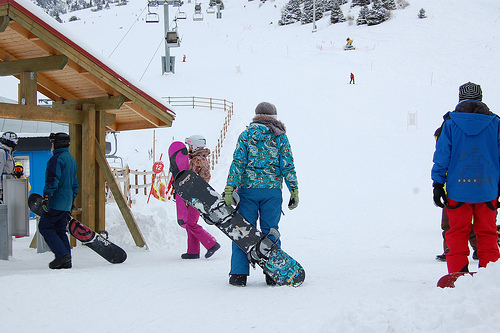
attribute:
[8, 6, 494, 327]
slope — covered with snow, for skiing, white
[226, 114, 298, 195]
parka — blue, colored, varied, patterned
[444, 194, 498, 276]
pants — for snow, red, snow style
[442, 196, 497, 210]
suspenders — attached to pants, hanging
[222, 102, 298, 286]
person — a woman, snowboarder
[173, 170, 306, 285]
snowboard — blue, black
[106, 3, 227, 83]
chairlift — for reaching top, for skiing, for trail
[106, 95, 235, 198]
fencing — wooden, rail style, wood, brown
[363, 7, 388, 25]
pine — snow covered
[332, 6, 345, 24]
pine — snow covered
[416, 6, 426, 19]
pine — snow covered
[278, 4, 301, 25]
pine — snow covered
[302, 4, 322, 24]
pine — snow covered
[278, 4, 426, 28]
cluster — fir, of trees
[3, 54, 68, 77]
beam — for support, wood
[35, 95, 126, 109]
beam — for support, wood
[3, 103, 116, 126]
beam — for support, wood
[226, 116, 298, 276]
outfit — black, teal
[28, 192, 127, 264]
snowboard — red, black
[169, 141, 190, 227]
snowboard — black, pink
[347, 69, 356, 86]
man — snowboarder, wearing red, skiing, wearing jacket, snowboarding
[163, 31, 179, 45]
seat — a basket, for lifting, basket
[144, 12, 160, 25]
seat — a basket, for lifting, basket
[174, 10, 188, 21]
seat — a basket, for lifting, basket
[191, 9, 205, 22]
seat — a basket, for lifting, basket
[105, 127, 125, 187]
seat — a basket, for lifting, basket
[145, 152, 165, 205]
sign — orange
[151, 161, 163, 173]
number — 12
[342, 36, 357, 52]
man — wearing yellow, wearing jacket, skiing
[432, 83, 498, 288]
man — wearing blue, wearing red, person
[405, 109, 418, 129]
marker — for trail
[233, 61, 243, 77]
marker — for trail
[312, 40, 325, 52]
marker — for trail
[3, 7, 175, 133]
roof — platform, wooden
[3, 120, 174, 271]
break area — wood constructed, shelter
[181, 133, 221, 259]
woman — heading, person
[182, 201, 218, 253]
pants — pink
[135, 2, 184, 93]
wire — guy type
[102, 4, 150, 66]
wire — guy type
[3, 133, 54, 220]
building — blue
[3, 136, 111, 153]
roof — metal, grey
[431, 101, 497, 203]
jacket — blue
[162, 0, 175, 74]
pole — for lifting, for skiing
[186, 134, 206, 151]
helmet — white